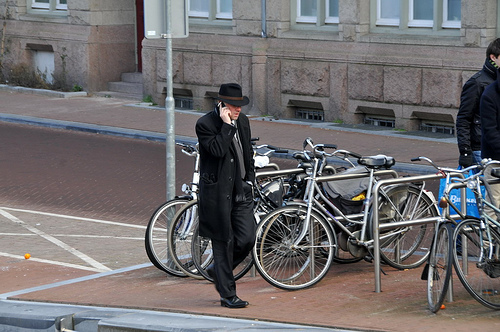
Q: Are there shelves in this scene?
A: No, there are no shelves.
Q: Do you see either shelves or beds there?
A: No, there are no shelves or beds.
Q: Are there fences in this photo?
A: No, there are no fences.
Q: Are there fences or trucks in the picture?
A: No, there are no fences or trucks.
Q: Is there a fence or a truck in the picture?
A: No, there are no fences or trucks.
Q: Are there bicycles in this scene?
A: Yes, there are bicycles.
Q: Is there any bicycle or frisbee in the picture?
A: Yes, there are bicycles.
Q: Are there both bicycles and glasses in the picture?
A: No, there are bicycles but no glasses.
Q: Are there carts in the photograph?
A: No, there are no carts.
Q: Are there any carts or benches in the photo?
A: No, there are no carts or benches.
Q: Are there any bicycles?
A: Yes, there are bicycles.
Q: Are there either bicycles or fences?
A: Yes, there are bicycles.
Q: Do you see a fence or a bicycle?
A: Yes, there are bicycles.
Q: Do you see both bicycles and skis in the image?
A: No, there are bicycles but no skis.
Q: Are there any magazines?
A: No, there are no magazines.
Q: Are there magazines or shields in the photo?
A: No, there are no magazines or shields.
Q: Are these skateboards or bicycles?
A: These are bicycles.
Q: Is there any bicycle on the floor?
A: Yes, there are bicycles on the floor.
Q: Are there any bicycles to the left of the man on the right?
A: Yes, there are bicycles to the left of the man.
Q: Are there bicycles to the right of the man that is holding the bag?
A: No, the bicycles are to the left of the man.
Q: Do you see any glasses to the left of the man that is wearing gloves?
A: No, there are bicycles to the left of the man.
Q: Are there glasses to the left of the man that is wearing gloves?
A: No, there are bicycles to the left of the man.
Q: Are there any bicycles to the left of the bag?
A: Yes, there are bicycles to the left of the bag.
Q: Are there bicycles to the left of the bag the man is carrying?
A: Yes, there are bicycles to the left of the bag.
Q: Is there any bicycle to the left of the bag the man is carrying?
A: Yes, there are bicycles to the left of the bag.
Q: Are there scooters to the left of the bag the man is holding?
A: No, there are bicycles to the left of the bag.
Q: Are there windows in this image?
A: Yes, there are windows.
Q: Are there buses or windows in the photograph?
A: Yes, there are windows.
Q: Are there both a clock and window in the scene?
A: No, there are windows but no clocks.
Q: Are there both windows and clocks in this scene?
A: No, there are windows but no clocks.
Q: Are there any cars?
A: No, there are no cars.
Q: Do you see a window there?
A: Yes, there are windows.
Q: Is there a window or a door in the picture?
A: Yes, there are windows.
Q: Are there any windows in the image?
A: Yes, there are windows.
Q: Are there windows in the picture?
A: Yes, there are windows.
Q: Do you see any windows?
A: Yes, there are windows.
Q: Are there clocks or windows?
A: Yes, there are windows.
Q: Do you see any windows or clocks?
A: Yes, there are windows.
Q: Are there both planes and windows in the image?
A: No, there are windows but no airplanes.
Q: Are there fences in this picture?
A: No, there are no fences.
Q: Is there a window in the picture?
A: Yes, there are windows.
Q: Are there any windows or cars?
A: Yes, there are windows.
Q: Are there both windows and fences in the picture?
A: No, there are windows but no fences.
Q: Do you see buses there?
A: No, there are no buses.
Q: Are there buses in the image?
A: No, there are no buses.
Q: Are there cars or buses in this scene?
A: No, there are no buses or cars.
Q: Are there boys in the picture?
A: No, there are no boys.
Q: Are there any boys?
A: No, there are no boys.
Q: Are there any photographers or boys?
A: No, there are no boys or photographers.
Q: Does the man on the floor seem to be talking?
A: Yes, the man is talking.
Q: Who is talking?
A: The man is talking.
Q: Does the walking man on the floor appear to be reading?
A: No, the man is talking.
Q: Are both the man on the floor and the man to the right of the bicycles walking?
A: Yes, both the man and the man are walking.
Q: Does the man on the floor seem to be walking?
A: Yes, the man is walking.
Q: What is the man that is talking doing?
A: The man is walking.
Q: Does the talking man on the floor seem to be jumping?
A: No, the man is walking.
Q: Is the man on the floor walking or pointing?
A: The man is walking.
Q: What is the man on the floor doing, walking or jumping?
A: The man is walking.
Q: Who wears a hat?
A: The man wears a hat.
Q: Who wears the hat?
A: The man wears a hat.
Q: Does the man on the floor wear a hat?
A: Yes, the man wears a hat.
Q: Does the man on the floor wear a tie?
A: No, the man wears a hat.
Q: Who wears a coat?
A: The man wears a coat.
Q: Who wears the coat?
A: The man wears a coat.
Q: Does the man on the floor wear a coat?
A: Yes, the man wears a coat.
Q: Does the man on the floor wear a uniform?
A: No, the man wears a coat.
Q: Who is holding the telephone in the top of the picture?
A: The man is holding the telephone.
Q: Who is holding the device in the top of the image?
A: The man is holding the telephone.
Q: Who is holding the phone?
A: The man is holding the telephone.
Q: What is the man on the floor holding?
A: The man is holding the phone.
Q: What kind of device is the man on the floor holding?
A: The man is holding the telephone.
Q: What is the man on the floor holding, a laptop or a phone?
A: The man is holding a phone.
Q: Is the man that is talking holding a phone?
A: Yes, the man is holding a phone.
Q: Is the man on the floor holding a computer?
A: No, the man is holding a phone.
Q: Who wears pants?
A: The man wears pants.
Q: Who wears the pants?
A: The man wears pants.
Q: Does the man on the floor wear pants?
A: Yes, the man wears pants.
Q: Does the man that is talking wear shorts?
A: No, the man wears pants.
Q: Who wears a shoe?
A: The man wears a shoe.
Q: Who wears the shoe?
A: The man wears a shoe.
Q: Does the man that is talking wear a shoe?
A: Yes, the man wears a shoe.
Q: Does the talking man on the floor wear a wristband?
A: No, the man wears a shoe.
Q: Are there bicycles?
A: Yes, there are bicycles.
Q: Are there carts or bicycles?
A: Yes, there are bicycles.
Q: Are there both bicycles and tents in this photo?
A: No, there are bicycles but no tents.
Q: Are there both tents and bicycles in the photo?
A: No, there are bicycles but no tents.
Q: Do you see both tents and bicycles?
A: No, there are bicycles but no tents.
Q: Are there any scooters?
A: No, there are no scooters.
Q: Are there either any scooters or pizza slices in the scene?
A: No, there are no scooters or pizza slices.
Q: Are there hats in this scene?
A: Yes, there is a hat.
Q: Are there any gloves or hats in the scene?
A: Yes, there is a hat.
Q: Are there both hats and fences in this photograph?
A: No, there is a hat but no fences.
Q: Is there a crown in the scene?
A: No, there are no crowns.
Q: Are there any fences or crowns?
A: No, there are no crowns or fences.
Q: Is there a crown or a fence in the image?
A: No, there are no crowns or fences.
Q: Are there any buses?
A: No, there are no buses.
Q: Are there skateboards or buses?
A: No, there are no buses or skateboards.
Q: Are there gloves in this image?
A: Yes, there are gloves.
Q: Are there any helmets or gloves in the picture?
A: Yes, there are gloves.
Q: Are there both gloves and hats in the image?
A: Yes, there are both gloves and a hat.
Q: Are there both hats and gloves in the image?
A: Yes, there are both gloves and a hat.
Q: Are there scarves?
A: No, there are no scarves.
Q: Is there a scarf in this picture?
A: No, there are no scarves.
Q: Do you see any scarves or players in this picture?
A: No, there are no scarves or players.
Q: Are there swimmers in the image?
A: No, there are no swimmers.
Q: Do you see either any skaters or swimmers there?
A: No, there are no swimmers or skaters.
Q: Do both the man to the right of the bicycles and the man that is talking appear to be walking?
A: Yes, both the man and the man are walking.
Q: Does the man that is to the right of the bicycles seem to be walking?
A: Yes, the man is walking.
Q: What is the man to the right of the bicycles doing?
A: The man is walking.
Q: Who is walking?
A: The man is walking.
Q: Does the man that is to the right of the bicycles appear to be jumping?
A: No, the man is walking.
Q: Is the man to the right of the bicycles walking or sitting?
A: The man is walking.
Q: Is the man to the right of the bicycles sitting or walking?
A: The man is walking.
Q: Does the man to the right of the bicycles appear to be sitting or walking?
A: The man is walking.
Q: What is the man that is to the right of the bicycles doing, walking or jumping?
A: The man is walking.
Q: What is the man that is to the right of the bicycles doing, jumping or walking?
A: The man is walking.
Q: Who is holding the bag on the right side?
A: The man is holding the bag.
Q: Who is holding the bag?
A: The man is holding the bag.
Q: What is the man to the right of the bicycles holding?
A: The man is holding the bag.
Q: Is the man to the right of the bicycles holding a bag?
A: Yes, the man is holding a bag.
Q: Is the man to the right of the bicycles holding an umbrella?
A: No, the man is holding a bag.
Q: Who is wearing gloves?
A: The man is wearing gloves.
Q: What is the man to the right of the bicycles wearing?
A: The man is wearing gloves.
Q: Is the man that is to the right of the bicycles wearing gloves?
A: Yes, the man is wearing gloves.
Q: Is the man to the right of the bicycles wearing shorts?
A: No, the man is wearing gloves.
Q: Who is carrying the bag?
A: The man is carrying the bag.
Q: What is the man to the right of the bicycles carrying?
A: The man is carrying a bag.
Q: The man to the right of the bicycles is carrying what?
A: The man is carrying a bag.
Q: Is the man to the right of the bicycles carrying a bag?
A: Yes, the man is carrying a bag.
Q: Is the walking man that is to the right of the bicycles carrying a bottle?
A: No, the man is carrying a bag.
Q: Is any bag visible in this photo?
A: Yes, there is a bag.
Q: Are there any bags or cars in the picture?
A: Yes, there is a bag.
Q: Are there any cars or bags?
A: Yes, there is a bag.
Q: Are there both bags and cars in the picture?
A: No, there is a bag but no cars.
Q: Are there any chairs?
A: No, there are no chairs.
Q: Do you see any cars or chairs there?
A: No, there are no chairs or cars.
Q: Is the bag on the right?
A: Yes, the bag is on the right of the image.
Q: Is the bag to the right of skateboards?
A: No, the bag is to the right of the bicycles.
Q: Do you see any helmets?
A: No, there are no helmets.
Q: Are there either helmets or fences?
A: No, there are no helmets or fences.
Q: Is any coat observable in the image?
A: Yes, there is a coat.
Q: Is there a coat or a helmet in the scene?
A: Yes, there is a coat.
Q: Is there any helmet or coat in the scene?
A: Yes, there is a coat.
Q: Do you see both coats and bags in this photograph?
A: Yes, there are both a coat and a bag.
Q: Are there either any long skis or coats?
A: Yes, there is a long coat.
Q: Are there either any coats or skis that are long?
A: Yes, the coat is long.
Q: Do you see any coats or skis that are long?
A: Yes, the coat is long.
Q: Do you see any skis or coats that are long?
A: Yes, the coat is long.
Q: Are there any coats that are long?
A: Yes, there is a long coat.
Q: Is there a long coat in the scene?
A: Yes, there is a long coat.